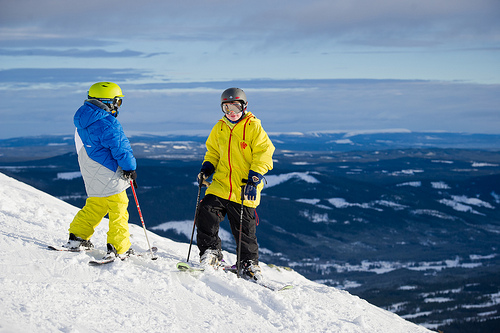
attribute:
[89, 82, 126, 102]
helmet — yellow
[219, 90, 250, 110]
helmet — grey, silver, gray, black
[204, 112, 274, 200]
jacket — yellow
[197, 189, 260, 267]
pants — black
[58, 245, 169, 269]
skis — paired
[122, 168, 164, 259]
pole — red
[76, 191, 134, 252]
pants — yellow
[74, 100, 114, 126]
hood — blue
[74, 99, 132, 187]
jacket — blue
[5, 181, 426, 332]
ground — covered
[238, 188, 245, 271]
pole — black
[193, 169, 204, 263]
pole — black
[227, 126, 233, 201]
zipper — red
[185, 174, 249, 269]
poles — black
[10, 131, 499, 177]
mountains — snowy, blue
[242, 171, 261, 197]
glove — blue